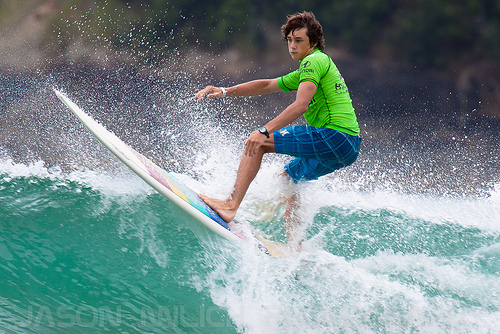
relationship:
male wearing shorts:
[194, 10, 362, 251] [271, 121, 363, 185]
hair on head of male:
[282, 12, 327, 47] [190, 11, 365, 221]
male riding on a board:
[194, 10, 362, 251] [50, 83, 295, 268]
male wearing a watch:
[194, 10, 362, 251] [250, 118, 275, 142]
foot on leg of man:
[182, 180, 254, 241] [164, 0, 376, 287]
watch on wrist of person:
[256, 115, 272, 145] [182, 10, 364, 263]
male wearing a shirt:
[194, 10, 362, 251] [264, 44, 380, 147]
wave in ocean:
[24, 156, 491, 324] [15, 159, 91, 331]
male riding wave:
[194, 10, 362, 251] [52, 140, 496, 332]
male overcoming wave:
[194, 10, 362, 251] [6, 137, 498, 332]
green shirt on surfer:
[277, 48, 360, 136] [215, 16, 356, 191]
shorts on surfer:
[272, 126, 362, 181] [215, 13, 375, 253]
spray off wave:
[375, 128, 487, 197] [55, 175, 489, 320]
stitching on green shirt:
[319, 60, 331, 90] [279, 55, 359, 135]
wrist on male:
[219, 90, 237, 102] [194, 10, 362, 251]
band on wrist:
[216, 85, 228, 101] [219, 90, 237, 102]